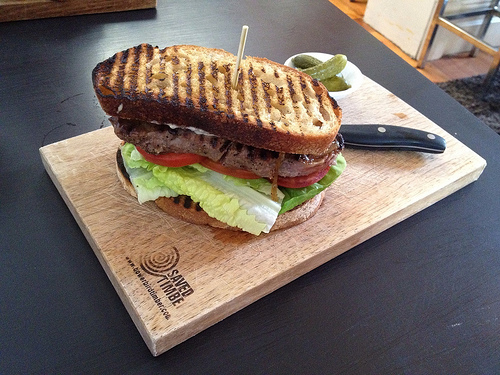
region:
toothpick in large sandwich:
[226, 20, 251, 90]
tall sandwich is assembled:
[81, 38, 353, 238]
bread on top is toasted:
[83, 35, 351, 163]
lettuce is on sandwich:
[119, 140, 287, 242]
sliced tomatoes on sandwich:
[133, 143, 338, 195]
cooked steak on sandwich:
[109, 115, 349, 188]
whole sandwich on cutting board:
[83, 33, 350, 238]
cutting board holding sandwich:
[37, 43, 492, 359]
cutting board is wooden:
[33, 39, 494, 359]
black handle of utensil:
[331, 115, 451, 163]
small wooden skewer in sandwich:
[228, 21, 250, 91]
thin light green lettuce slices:
[113, 137, 285, 237]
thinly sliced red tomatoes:
[131, 142, 333, 190]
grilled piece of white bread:
[88, 37, 346, 157]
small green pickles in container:
[288, 52, 350, 97]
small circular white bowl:
[277, 49, 364, 106]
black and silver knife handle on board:
[329, 116, 450, 156]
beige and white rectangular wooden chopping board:
[33, 50, 490, 362]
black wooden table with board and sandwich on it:
[0, 0, 499, 374]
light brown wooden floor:
[321, 0, 498, 85]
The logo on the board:
[118, 241, 205, 329]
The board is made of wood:
[10, 48, 486, 345]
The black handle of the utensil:
[344, 120, 452, 162]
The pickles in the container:
[287, 48, 369, 97]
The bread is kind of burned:
[91, 34, 343, 147]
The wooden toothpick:
[228, 23, 260, 84]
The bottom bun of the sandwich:
[100, 157, 322, 242]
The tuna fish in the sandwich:
[136, 128, 336, 190]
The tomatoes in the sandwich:
[130, 150, 317, 200]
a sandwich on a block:
[112, 10, 409, 352]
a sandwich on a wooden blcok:
[112, 24, 387, 295]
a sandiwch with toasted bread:
[103, 20, 372, 230]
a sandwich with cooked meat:
[151, 81, 311, 191]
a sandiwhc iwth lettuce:
[157, 130, 281, 218]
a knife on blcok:
[294, 62, 476, 231]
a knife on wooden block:
[335, 104, 478, 211]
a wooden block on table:
[22, 81, 307, 368]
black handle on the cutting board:
[336, 118, 453, 158]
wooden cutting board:
[25, 50, 498, 357]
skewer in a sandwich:
[228, 21, 253, 87]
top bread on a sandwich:
[87, 38, 344, 153]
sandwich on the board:
[51, 30, 371, 240]